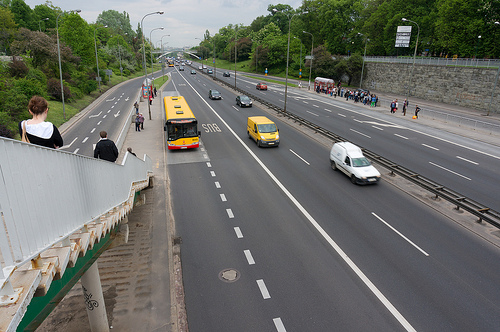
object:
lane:
[173, 62, 499, 328]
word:
[200, 122, 220, 132]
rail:
[0, 134, 147, 291]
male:
[95, 130, 120, 161]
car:
[256, 82, 267, 91]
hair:
[30, 100, 45, 113]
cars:
[235, 94, 252, 108]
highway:
[56, 58, 500, 314]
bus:
[163, 95, 201, 151]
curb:
[157, 142, 192, 329]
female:
[18, 93, 63, 148]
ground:
[354, 172, 385, 218]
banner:
[393, 24, 412, 48]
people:
[414, 105, 421, 117]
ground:
[373, 125, 409, 152]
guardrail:
[404, 166, 498, 228]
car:
[330, 142, 382, 186]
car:
[247, 115, 280, 148]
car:
[208, 89, 222, 101]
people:
[401, 102, 406, 115]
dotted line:
[265, 314, 291, 330]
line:
[213, 180, 226, 190]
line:
[370, 211, 429, 258]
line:
[285, 143, 311, 166]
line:
[350, 127, 373, 139]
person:
[407, 97, 409, 105]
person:
[391, 99, 395, 113]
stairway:
[0, 135, 151, 331]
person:
[128, 148, 139, 158]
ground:
[318, 98, 350, 122]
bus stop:
[121, 70, 173, 134]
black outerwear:
[92, 137, 118, 162]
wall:
[361, 59, 499, 114]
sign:
[395, 26, 413, 49]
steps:
[4, 121, 143, 329]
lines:
[219, 193, 227, 201]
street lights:
[69, 12, 84, 22]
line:
[252, 280, 277, 302]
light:
[155, 11, 166, 17]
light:
[157, 28, 165, 33]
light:
[165, 32, 174, 37]